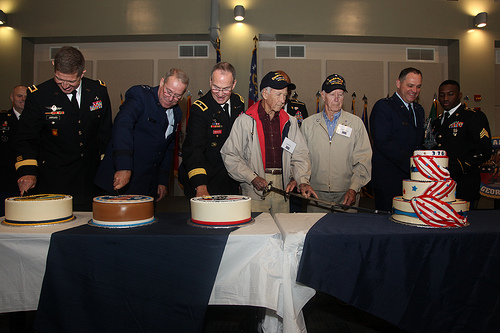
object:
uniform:
[429, 103, 493, 209]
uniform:
[321, 74, 349, 93]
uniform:
[260, 70, 296, 92]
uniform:
[177, 89, 245, 197]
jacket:
[220, 99, 312, 202]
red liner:
[258, 101, 282, 167]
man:
[220, 69, 319, 213]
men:
[10, 46, 492, 213]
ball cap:
[321, 73, 348, 93]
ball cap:
[260, 70, 297, 91]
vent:
[178, 44, 209, 58]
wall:
[0, 4, 498, 139]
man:
[371, 67, 425, 211]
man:
[428, 80, 492, 208]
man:
[177, 61, 245, 212]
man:
[9, 47, 112, 211]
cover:
[274, 212, 500, 333]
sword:
[252, 180, 389, 214]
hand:
[342, 192, 356, 210]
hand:
[300, 183, 318, 199]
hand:
[113, 170, 131, 190]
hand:
[17, 175, 36, 197]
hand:
[252, 176, 269, 191]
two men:
[367, 67, 493, 215]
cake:
[190, 195, 252, 226]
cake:
[92, 194, 155, 227]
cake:
[4, 193, 75, 226]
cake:
[392, 149, 470, 225]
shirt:
[322, 107, 340, 140]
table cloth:
[0, 211, 497, 333]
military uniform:
[424, 103, 491, 199]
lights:
[233, 5, 246, 21]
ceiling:
[11, 0, 225, 16]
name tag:
[335, 124, 352, 138]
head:
[320, 73, 345, 111]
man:
[95, 68, 189, 214]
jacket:
[93, 84, 182, 196]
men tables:
[0, 208, 500, 333]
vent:
[276, 45, 305, 58]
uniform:
[10, 77, 114, 209]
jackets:
[299, 110, 373, 194]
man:
[286, 73, 371, 215]